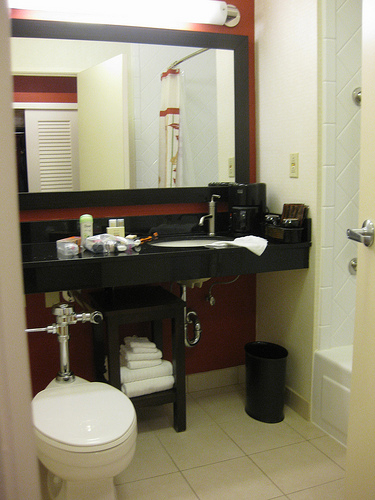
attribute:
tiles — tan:
[113, 383, 343, 498]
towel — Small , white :
[204, 234, 268, 254]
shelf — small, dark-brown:
[117, 320, 179, 403]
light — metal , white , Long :
[6, 2, 243, 29]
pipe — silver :
[180, 285, 204, 351]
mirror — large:
[12, 18, 250, 211]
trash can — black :
[243, 335, 286, 424]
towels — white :
[102, 334, 174, 397]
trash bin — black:
[239, 335, 288, 431]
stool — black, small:
[87, 282, 189, 431]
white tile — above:
[308, 46, 357, 136]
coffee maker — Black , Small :
[215, 178, 273, 238]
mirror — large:
[32, 28, 279, 211]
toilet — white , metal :
[31, 287, 157, 499]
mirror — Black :
[14, 22, 242, 198]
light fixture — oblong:
[2, 2, 239, 28]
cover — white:
[32, 2, 224, 23]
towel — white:
[124, 335, 155, 349]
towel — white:
[127, 345, 156, 352]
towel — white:
[118, 343, 162, 358]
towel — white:
[119, 358, 164, 365]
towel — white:
[117, 362, 171, 377]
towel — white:
[122, 375, 174, 396]